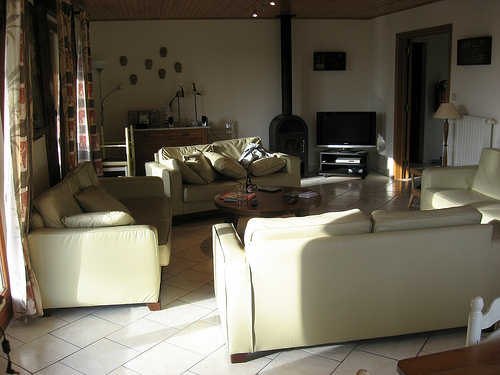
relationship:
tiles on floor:
[0, 160, 499, 374] [0, 170, 491, 374]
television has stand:
[316, 111, 377, 148] [318, 148, 369, 178]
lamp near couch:
[432, 101, 460, 166] [420, 147, 495, 230]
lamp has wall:
[94, 51, 131, 127] [87, 21, 274, 115]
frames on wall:
[309, 47, 349, 71] [86, 21, 373, 170]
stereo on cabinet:
[128, 111, 160, 128] [132, 114, 216, 176]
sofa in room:
[137, 123, 314, 230] [0, 0, 498, 374]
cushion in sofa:
[169, 157, 219, 172] [144, 142, 301, 199]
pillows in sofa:
[203, 150, 247, 180] [144, 135, 305, 209]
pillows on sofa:
[161, 141, 288, 183] [147, 128, 309, 218]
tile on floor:
[103, 316, 180, 353] [0, 170, 491, 374]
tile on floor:
[256, 349, 342, 374] [0, 170, 491, 374]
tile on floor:
[61, 337, 141, 373] [0, 170, 491, 374]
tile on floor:
[328, 348, 400, 373] [0, 170, 491, 374]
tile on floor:
[164, 319, 226, 356] [0, 170, 491, 374]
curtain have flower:
[3, 1, 42, 321] [12, 139, 34, 168]